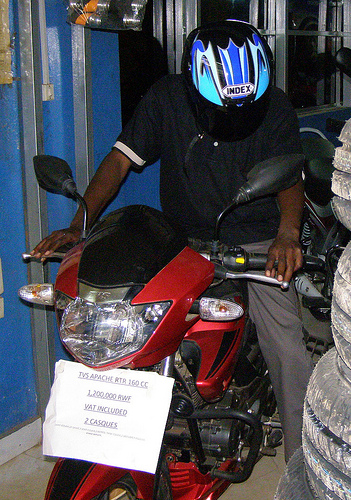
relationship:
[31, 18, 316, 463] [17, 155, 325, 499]
person on motorcycle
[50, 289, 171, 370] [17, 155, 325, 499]
headlight on motorcycle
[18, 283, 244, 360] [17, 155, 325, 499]
lights on motorcycle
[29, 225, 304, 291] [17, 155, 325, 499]
hands on motorcycle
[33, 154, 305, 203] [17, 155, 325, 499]
mirrors on motorcycle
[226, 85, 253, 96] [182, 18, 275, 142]
index on helmet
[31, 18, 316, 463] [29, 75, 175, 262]
person has an arm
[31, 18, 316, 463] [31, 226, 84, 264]
person has a hand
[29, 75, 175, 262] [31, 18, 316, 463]
arm on person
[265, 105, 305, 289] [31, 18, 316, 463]
arm on person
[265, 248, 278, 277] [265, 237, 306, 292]
finger on hand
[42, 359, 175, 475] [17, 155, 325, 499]
sign on motorcycle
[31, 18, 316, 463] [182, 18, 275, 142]
person wearing helmet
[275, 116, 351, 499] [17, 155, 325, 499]
tires next to motorcycle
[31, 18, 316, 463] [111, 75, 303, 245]
person wearing shirt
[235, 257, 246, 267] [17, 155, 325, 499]
button on motorcycle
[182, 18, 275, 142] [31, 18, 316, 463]
helmet on person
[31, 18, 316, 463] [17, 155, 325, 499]
person sitting on motorcycle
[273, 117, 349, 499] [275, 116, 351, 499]
dirt on tires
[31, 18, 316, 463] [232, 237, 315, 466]
person wearing pants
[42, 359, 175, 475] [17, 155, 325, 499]
paper on motorcycle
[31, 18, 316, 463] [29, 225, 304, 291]
person has hands